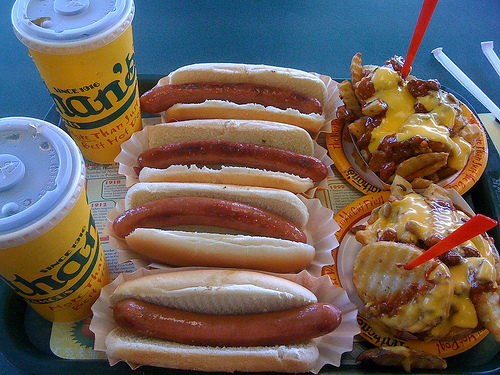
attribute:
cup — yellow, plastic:
[15, 4, 144, 164]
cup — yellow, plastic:
[5, 122, 102, 333]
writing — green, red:
[50, 66, 142, 135]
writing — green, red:
[15, 223, 107, 305]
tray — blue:
[8, 63, 497, 374]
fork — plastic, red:
[400, 0, 439, 84]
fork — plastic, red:
[401, 215, 498, 280]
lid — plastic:
[11, 0, 134, 54]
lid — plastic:
[1, 113, 87, 244]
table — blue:
[1, 2, 499, 374]